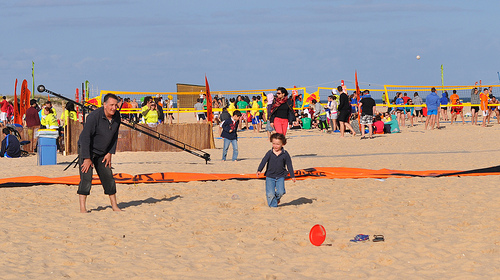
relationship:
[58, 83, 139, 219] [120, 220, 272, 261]
man in sand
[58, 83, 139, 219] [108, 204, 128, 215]
man bare foot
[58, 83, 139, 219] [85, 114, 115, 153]
man wearing gray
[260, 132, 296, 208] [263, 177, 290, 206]
boy wearing jeans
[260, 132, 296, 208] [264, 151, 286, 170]
boy wearing gray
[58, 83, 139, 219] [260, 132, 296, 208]
man and boy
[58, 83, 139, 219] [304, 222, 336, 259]
man with frisbee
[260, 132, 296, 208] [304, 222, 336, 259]
boy with frisbee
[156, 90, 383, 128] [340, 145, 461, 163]
people at beach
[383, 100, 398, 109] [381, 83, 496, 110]
yellow volleyball nets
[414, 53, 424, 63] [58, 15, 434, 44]
volleyball in sky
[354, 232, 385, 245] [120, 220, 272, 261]
sandals in sand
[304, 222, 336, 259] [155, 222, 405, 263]
frisbee on ground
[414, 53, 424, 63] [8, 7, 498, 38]
volleyball in air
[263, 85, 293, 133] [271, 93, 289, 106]
woman wearing scarf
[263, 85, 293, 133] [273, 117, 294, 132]
woman wearing pants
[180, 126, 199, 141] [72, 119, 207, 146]
section of fence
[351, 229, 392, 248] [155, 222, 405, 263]
flipflops on ground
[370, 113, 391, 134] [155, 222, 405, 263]
person on ground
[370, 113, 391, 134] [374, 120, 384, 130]
person wearing shirt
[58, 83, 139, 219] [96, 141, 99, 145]
man bending over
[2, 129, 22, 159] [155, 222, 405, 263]
person on ground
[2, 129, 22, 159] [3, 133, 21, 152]
person wearing shirt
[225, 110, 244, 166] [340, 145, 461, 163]
child on beach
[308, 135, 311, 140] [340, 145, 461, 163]
brown sandy beach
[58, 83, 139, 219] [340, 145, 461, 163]
man on beach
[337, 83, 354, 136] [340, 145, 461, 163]
man on beach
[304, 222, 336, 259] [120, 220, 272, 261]
frisbee on sand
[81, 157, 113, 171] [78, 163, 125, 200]
hands on legs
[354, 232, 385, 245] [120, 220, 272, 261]
shoes in sand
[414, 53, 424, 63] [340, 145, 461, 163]
volleyball on beach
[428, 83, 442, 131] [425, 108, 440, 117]
man wearing shorts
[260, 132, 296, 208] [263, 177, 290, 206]
child wearing jeans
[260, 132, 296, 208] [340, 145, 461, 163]
child on beach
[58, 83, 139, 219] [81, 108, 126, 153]
man wearing sweater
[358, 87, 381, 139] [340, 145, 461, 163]
person on beach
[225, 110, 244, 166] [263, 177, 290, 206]
child has jeans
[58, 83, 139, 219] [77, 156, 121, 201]
man has jeans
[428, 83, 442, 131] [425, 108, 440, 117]
man has shorts